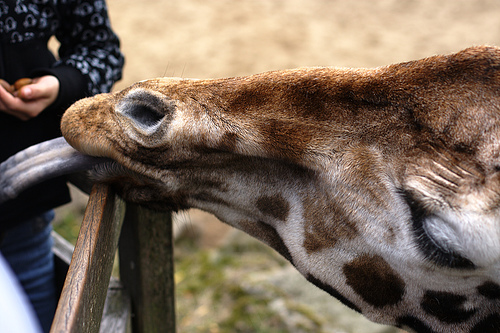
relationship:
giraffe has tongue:
[0, 45, 499, 329] [0, 135, 88, 198]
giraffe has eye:
[0, 45, 499, 329] [396, 182, 477, 273]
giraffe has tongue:
[0, 45, 499, 329] [2, 135, 92, 201]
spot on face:
[341, 250, 406, 310] [59, 46, 498, 331]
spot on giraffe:
[341, 250, 406, 310] [0, 45, 499, 329]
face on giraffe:
[59, 46, 498, 331] [0, 45, 499, 329]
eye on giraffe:
[396, 182, 477, 273] [0, 45, 499, 329]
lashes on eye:
[393, 184, 476, 271] [396, 182, 477, 273]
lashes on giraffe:
[393, 184, 476, 271] [0, 45, 499, 329]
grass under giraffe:
[57, 200, 407, 331] [0, 45, 499, 329]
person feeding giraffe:
[2, 1, 124, 333] [0, 45, 499, 329]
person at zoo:
[2, 1, 124, 333] [0, 0, 498, 330]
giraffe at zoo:
[0, 45, 499, 329] [0, 0, 498, 330]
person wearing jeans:
[2, 1, 124, 333] [3, 210, 52, 331]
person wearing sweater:
[2, 1, 124, 333] [2, 1, 125, 213]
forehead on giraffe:
[164, 47, 499, 191] [0, 45, 499, 329]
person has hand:
[2, 1, 124, 333] [2, 75, 59, 115]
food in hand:
[9, 77, 36, 95] [2, 75, 59, 115]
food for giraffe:
[9, 77, 36, 95] [0, 45, 499, 329]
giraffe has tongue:
[0, 45, 499, 329] [0, 136, 96, 197]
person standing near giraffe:
[2, 1, 124, 331] [0, 45, 499, 329]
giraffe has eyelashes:
[0, 45, 499, 329] [392, 186, 475, 273]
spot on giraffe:
[298, 174, 364, 258] [0, 45, 499, 329]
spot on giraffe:
[237, 178, 293, 230] [57, 24, 467, 330]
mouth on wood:
[49, 107, 135, 187] [52, 180, 139, 327]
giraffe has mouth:
[0, 45, 499, 329] [49, 107, 135, 187]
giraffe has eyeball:
[0, 45, 499, 329] [411, 193, 478, 269]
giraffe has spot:
[0, 45, 499, 329] [341, 250, 408, 310]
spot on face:
[341, 250, 408, 310] [226, 144, 469, 330]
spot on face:
[251, 189, 292, 222] [284, 184, 389, 294]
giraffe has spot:
[0, 45, 499, 329] [251, 189, 292, 222]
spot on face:
[412, 283, 480, 325] [273, 180, 394, 311]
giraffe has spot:
[0, 45, 499, 329] [412, 283, 480, 325]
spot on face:
[256, 188, 295, 224] [273, 180, 394, 311]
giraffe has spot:
[0, 45, 499, 329] [256, 188, 295, 224]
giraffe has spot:
[0, 45, 499, 329] [253, 184, 285, 225]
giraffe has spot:
[0, 45, 499, 329] [347, 243, 401, 312]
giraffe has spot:
[0, 45, 499, 329] [423, 283, 470, 321]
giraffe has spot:
[0, 45, 499, 329] [254, 190, 287, 218]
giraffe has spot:
[0, 45, 499, 329] [424, 282, 472, 328]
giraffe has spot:
[0, 45, 499, 329] [422, 289, 465, 320]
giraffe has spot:
[0, 45, 499, 329] [338, 247, 404, 313]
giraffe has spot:
[0, 45, 499, 329] [255, 190, 291, 223]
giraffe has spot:
[0, 45, 499, 329] [342, 250, 403, 313]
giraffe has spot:
[0, 45, 499, 329] [417, 278, 472, 328]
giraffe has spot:
[0, 45, 499, 329] [341, 242, 404, 312]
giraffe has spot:
[0, 45, 499, 329] [417, 292, 472, 324]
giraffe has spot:
[0, 45, 499, 329] [422, 290, 473, 324]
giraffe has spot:
[0, 45, 499, 329] [337, 240, 407, 315]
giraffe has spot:
[0, 45, 499, 329] [419, 287, 471, 331]